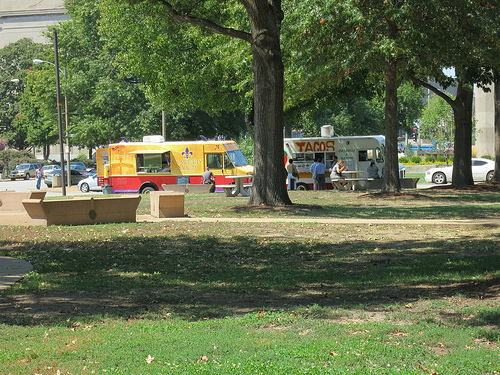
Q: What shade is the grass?
A: Green.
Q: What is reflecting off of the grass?
A: Shadow.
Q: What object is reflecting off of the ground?
A: Tree.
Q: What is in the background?
A: Trucks.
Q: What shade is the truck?
A: Red and yellow.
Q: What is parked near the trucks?
A: Cars.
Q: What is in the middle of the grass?
A: Tree trunk.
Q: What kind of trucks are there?
A: Food trucks.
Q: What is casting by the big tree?
A: Shadow.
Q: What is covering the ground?
A: Grass with leaves.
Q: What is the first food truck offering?
A: Tacos.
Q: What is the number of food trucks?
A: Two.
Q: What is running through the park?
A: A sidewalk.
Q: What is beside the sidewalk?
A: Benches for sitting.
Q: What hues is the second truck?
A: Yellow and red.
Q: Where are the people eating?
A: The tables.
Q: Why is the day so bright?
A: The sun is shining.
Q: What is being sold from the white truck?
A: Tacos.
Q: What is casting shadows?
A: Trees.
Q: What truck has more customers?
A: Taco truck.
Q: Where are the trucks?
A: At a park.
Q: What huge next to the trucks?
A: The green tree.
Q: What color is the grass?
A: Green.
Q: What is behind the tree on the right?
A: A white car.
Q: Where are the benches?
A: On the left.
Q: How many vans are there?
A: Two.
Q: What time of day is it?
A: Day time.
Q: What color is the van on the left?
A: Yellow and red.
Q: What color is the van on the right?
A: White.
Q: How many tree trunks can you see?
A: Three.